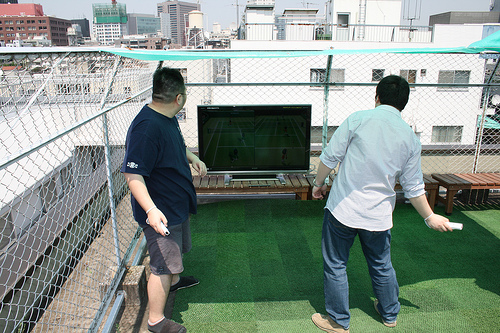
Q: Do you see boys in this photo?
A: No, there are no boys.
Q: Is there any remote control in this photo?
A: Yes, there is a remote control.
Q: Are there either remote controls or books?
A: Yes, there is a remote control.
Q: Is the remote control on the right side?
A: Yes, the remote control is on the right of the image.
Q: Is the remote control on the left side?
A: No, the remote control is on the right of the image.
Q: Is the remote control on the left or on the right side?
A: The remote control is on the right of the image.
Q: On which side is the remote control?
A: The remote control is on the right of the image.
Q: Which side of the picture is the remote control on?
A: The remote control is on the right of the image.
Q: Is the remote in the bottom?
A: Yes, the remote is in the bottom of the image.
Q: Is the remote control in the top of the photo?
A: No, the remote control is in the bottom of the image.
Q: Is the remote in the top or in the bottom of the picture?
A: The remote is in the bottom of the image.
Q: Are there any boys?
A: No, there are no boys.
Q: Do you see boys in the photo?
A: No, there are no boys.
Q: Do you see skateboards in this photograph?
A: No, there are no skateboards.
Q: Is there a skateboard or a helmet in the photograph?
A: No, there are no skateboards or helmets.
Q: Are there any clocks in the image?
A: No, there are no clocks.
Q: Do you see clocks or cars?
A: No, there are no clocks or cars.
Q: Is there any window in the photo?
A: Yes, there is a window.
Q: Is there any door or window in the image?
A: Yes, there is a window.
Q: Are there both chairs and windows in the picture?
A: No, there is a window but no chairs.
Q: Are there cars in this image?
A: No, there are no cars.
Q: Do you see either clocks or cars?
A: No, there are no cars or clocks.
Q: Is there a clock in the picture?
A: No, there are no clocks.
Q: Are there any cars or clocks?
A: No, there are no clocks or cars.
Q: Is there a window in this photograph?
A: Yes, there is a window.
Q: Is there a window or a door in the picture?
A: Yes, there is a window.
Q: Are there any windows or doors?
A: Yes, there is a window.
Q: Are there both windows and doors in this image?
A: No, there is a window but no doors.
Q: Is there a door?
A: No, there are no doors.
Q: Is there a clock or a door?
A: No, there are no doors or clocks.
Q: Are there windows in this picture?
A: Yes, there is a window.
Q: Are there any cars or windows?
A: Yes, there is a window.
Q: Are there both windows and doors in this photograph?
A: No, there is a window but no doors.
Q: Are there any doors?
A: No, there are no doors.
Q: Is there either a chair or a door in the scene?
A: No, there are no doors or chairs.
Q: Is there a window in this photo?
A: Yes, there is a window.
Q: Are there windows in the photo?
A: Yes, there is a window.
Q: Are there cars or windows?
A: Yes, there is a window.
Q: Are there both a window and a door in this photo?
A: No, there is a window but no doors.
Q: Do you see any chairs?
A: No, there are no chairs.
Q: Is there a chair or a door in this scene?
A: No, there are no chairs or doors.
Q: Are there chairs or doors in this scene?
A: No, there are no chairs or doors.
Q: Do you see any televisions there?
A: Yes, there is a television.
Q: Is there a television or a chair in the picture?
A: Yes, there is a television.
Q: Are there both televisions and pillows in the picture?
A: No, there is a television but no pillows.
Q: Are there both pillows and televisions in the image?
A: No, there is a television but no pillows.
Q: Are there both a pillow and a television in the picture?
A: No, there is a television but no pillows.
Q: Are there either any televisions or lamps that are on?
A: Yes, the television is on.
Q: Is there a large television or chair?
A: Yes, there is a large television.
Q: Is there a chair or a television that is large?
A: Yes, the television is large.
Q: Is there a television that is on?
A: Yes, there is a television that is on.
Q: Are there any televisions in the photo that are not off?
A: Yes, there is a television that is on.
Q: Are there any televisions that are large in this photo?
A: Yes, there is a large television.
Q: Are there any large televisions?
A: Yes, there is a large television.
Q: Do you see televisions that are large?
A: Yes, there is a television that is large.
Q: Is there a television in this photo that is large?
A: Yes, there is a television that is large.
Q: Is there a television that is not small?
A: Yes, there is a large television.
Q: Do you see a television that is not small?
A: Yes, there is a large television.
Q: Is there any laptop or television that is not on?
A: No, there is a television but it is on.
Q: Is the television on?
A: Yes, the television is on.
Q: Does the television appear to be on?
A: Yes, the television is on.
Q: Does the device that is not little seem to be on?
A: Yes, the television is on.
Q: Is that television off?
A: No, the television is on.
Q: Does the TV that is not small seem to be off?
A: No, the TV is on.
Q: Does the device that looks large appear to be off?
A: No, the TV is on.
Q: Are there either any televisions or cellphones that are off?
A: No, there is a television but it is on.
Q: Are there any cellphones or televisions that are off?
A: No, there is a television but it is on.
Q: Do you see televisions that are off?
A: No, there is a television but it is on.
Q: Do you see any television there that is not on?
A: No, there is a television but it is on.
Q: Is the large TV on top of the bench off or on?
A: The TV is on.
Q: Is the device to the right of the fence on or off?
A: The TV is on.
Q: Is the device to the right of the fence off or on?
A: The TV is on.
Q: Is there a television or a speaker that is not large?
A: No, there is a television but it is large.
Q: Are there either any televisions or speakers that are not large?
A: No, there is a television but it is large.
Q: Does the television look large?
A: Yes, the television is large.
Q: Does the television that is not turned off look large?
A: Yes, the TV is large.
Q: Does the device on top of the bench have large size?
A: Yes, the TV is large.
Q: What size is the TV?
A: The TV is large.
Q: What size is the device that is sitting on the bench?
A: The TV is large.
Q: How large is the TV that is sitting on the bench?
A: The television is large.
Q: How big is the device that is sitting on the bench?
A: The television is large.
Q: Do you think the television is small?
A: No, the television is large.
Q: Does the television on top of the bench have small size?
A: No, the TV is large.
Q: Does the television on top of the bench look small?
A: No, the TV is large.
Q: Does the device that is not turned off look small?
A: No, the TV is large.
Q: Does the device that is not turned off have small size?
A: No, the TV is large.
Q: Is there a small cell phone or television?
A: No, there is a television but it is large.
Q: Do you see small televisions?
A: No, there is a television but it is large.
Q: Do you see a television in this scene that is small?
A: No, there is a television but it is large.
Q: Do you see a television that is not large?
A: No, there is a television but it is large.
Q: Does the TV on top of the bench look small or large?
A: The television is large.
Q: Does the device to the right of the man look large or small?
A: The television is large.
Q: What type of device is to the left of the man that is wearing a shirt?
A: The device is a television.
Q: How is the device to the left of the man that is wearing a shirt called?
A: The device is a television.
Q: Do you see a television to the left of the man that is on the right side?
A: Yes, there is a television to the left of the man.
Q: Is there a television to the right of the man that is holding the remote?
A: No, the television is to the left of the man.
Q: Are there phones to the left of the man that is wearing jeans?
A: No, there is a television to the left of the man.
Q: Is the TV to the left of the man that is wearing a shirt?
A: Yes, the TV is to the left of the man.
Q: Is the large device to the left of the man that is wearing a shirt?
A: Yes, the TV is to the left of the man.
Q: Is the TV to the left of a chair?
A: No, the TV is to the left of the man.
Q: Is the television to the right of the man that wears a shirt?
A: No, the television is to the left of the man.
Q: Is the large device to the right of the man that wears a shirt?
A: No, the television is to the left of the man.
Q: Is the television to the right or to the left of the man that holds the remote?
A: The television is to the left of the man.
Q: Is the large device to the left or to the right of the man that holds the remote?
A: The television is to the left of the man.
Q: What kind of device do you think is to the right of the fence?
A: The device is a television.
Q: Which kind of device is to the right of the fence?
A: The device is a television.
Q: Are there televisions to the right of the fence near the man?
A: Yes, there is a television to the right of the fence.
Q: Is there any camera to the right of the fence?
A: No, there is a television to the right of the fence.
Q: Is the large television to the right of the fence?
A: Yes, the TV is to the right of the fence.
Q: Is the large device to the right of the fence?
A: Yes, the TV is to the right of the fence.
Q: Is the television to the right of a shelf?
A: No, the television is to the right of the fence.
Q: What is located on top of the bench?
A: The TV is on top of the bench.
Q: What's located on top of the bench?
A: The TV is on top of the bench.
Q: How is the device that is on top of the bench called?
A: The device is a television.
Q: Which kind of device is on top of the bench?
A: The device is a television.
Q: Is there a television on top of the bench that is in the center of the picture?
A: Yes, there is a television on top of the bench.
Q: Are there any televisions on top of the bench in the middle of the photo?
A: Yes, there is a television on top of the bench.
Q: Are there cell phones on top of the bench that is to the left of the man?
A: No, there is a television on top of the bench.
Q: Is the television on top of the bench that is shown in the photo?
A: Yes, the television is on top of the bench.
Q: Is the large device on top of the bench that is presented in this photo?
A: Yes, the television is on top of the bench.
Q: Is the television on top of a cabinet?
A: No, the television is on top of the bench.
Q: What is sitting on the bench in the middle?
A: The TV is sitting on the bench.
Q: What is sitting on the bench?
A: The TV is sitting on the bench.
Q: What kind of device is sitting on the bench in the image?
A: The device is a television.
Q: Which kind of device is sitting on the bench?
A: The device is a television.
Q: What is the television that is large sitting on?
A: The television is sitting on the bench.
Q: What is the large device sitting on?
A: The television is sitting on the bench.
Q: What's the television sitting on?
A: The television is sitting on the bench.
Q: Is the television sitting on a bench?
A: Yes, the television is sitting on a bench.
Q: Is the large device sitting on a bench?
A: Yes, the television is sitting on a bench.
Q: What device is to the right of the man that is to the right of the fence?
A: The device is a television.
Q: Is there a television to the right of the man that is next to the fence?
A: Yes, there is a television to the right of the man.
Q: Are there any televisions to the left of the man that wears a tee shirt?
A: No, the television is to the right of the man.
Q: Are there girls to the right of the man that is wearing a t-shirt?
A: No, there is a television to the right of the man.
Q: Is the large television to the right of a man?
A: Yes, the TV is to the right of a man.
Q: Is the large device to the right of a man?
A: Yes, the TV is to the right of a man.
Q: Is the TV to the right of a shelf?
A: No, the TV is to the right of a man.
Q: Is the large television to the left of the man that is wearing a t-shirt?
A: No, the TV is to the right of the man.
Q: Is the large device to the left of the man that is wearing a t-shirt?
A: No, the TV is to the right of the man.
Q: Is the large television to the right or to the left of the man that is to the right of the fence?
A: The TV is to the right of the man.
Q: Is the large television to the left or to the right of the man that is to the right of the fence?
A: The TV is to the right of the man.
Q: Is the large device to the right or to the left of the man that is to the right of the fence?
A: The TV is to the right of the man.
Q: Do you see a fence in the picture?
A: Yes, there is a fence.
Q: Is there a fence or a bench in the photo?
A: Yes, there is a fence.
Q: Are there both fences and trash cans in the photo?
A: No, there is a fence but no trash cans.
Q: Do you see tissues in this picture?
A: No, there are no tissues.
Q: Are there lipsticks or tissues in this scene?
A: No, there are no tissues or lipsticks.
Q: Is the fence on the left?
A: Yes, the fence is on the left of the image.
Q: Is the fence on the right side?
A: No, the fence is on the left of the image.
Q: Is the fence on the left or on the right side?
A: The fence is on the left of the image.